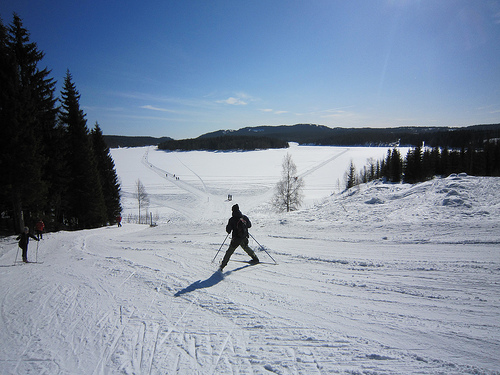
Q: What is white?
A: Snow.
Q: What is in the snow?
A: Tracks.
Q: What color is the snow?
A: White.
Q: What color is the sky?
A: Blue.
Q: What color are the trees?
A: Green.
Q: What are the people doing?
A: Skiing.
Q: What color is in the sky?
A: Clear and blue.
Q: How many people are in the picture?
A: Three.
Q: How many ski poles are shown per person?
A: Two.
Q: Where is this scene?
A: Ski slope.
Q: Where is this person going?
A: Downhill.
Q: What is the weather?
A: Clear, cold and sunny.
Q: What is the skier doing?
A: The snow-plow.